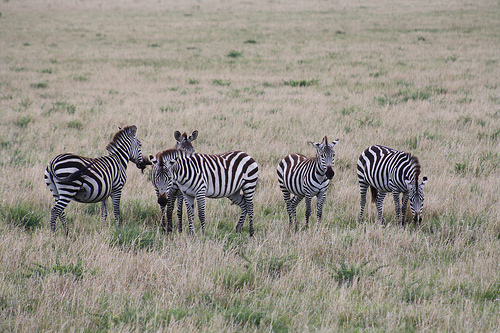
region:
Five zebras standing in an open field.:
[0, 2, 498, 331]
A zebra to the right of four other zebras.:
[355, 141, 431, 232]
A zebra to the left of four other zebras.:
[43, 125, 148, 232]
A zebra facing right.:
[40, 125, 147, 230]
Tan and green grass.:
[0, 0, 497, 331]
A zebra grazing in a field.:
[354, 141, 431, 238]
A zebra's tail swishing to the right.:
[48, 158, 101, 183]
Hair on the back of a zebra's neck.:
[154, 148, 194, 159]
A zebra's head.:
[306, 133, 339, 183]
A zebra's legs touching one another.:
[235, 195, 258, 237]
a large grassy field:
[0, 0, 498, 332]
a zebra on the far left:
[43, 124, 145, 234]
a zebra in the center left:
[148, 148, 258, 237]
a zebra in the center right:
[276, 135, 338, 230]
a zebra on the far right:
[355, 144, 427, 228]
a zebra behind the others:
[140, 128, 198, 234]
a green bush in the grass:
[324, 257, 391, 286]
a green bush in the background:
[224, 47, 244, 58]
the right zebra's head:
[402, 175, 427, 225]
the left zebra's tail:
[50, 152, 99, 183]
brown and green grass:
[3, 2, 496, 329]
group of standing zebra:
[47, 123, 428, 240]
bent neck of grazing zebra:
[356, 144, 428, 223]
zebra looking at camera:
[277, 135, 338, 225]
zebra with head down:
[146, 150, 258, 235]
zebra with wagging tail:
[44, 125, 140, 235]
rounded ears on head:
[172, 130, 197, 150]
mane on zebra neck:
[107, 125, 134, 157]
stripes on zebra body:
[177, 152, 256, 197]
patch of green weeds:
[328, 259, 389, 289]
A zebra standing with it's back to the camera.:
[29, 116, 151, 215]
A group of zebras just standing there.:
[36, 109, 437, 264]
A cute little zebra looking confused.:
[274, 138, 343, 229]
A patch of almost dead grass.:
[228, 238, 392, 315]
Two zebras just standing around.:
[155, 117, 262, 240]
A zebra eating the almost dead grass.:
[354, 134, 422, 230]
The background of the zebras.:
[49, 75, 336, 128]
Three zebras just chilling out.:
[21, 107, 271, 243]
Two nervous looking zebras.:
[267, 124, 427, 227]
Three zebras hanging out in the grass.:
[148, 102, 353, 228]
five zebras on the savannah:
[10, 6, 498, 331]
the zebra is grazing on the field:
[355, 136, 435, 248]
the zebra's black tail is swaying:
[47, 155, 99, 184]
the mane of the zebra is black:
[406, 150, 426, 196]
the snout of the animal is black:
[322, 163, 335, 182]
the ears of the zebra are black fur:
[171, 128, 199, 143]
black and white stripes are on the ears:
[143, 151, 181, 176]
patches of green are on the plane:
[17, 65, 493, 327]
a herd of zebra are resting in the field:
[37, 115, 435, 257]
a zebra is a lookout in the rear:
[165, 125, 205, 160]